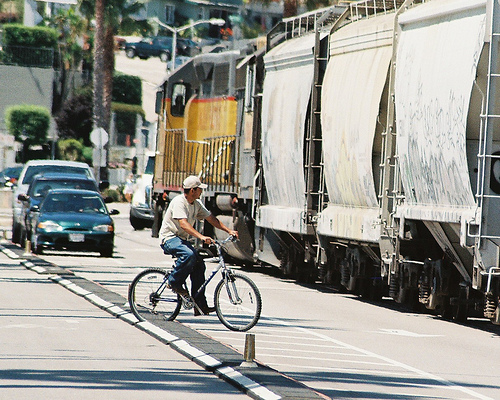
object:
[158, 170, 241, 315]
man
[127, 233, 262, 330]
bike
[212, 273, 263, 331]
tire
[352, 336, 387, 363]
mark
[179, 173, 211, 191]
cap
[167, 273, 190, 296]
foot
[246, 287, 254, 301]
reflectors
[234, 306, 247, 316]
spike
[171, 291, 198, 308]
pedal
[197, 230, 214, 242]
hand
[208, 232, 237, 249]
handle bar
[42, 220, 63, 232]
light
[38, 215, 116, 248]
front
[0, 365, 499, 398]
shadow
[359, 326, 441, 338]
arrow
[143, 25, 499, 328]
train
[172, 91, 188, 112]
driver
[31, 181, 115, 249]
car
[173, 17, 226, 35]
lamp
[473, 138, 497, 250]
ladder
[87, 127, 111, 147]
sign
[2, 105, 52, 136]
bush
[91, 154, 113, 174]
post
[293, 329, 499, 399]
road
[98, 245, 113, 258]
wheel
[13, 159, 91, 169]
car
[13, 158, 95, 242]
truck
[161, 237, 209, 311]
jeans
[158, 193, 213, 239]
shirt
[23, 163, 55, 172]
front